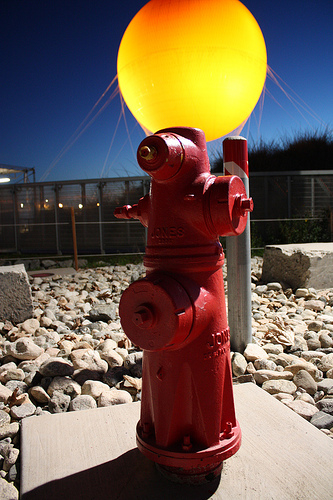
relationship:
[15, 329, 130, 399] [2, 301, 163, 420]
rocks on ground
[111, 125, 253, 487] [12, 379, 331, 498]
fire hydrant on base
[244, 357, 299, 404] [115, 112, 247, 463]
stones around hydrant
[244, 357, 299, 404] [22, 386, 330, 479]
stones around base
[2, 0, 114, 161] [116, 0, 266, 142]
sky around balloon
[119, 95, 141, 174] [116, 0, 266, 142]
line hold balloon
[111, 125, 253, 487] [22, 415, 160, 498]
fire hydrant on slab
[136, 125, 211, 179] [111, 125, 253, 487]
top of fire hydrant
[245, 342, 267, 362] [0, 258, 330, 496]
rock on ground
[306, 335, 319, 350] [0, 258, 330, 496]
rock on ground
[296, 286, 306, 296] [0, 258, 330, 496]
rock on ground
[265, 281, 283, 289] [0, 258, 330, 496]
rock on ground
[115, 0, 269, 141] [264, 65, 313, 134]
baloon with rope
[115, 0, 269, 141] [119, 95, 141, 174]
baloon with line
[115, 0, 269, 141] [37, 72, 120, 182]
baloon with line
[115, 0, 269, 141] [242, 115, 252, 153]
baloon with rope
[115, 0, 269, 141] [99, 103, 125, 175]
baloon with line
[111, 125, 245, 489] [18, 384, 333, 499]
fire hydrant on base